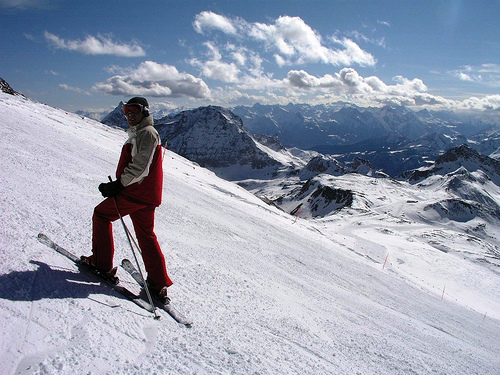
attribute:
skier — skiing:
[80, 97, 172, 306]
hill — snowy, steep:
[0, 76, 499, 374]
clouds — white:
[25, 12, 500, 111]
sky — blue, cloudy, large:
[0, 0, 499, 122]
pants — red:
[92, 193, 173, 295]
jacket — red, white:
[116, 116, 163, 206]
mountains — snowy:
[100, 101, 499, 175]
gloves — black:
[99, 175, 126, 198]